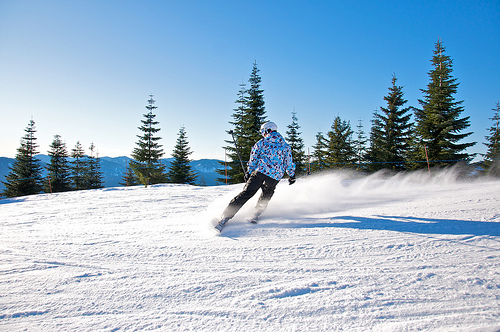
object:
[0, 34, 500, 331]
landscape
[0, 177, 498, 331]
snow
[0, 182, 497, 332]
ground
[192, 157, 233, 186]
hills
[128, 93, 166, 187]
pine trees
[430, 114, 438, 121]
pine needles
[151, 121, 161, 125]
branches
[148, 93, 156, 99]
tree tops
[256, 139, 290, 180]
back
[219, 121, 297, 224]
skiier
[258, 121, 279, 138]
helmet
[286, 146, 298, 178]
arm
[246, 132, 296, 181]
jacket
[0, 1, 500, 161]
sky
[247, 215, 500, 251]
shadow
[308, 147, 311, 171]
poles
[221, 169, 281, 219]
black pants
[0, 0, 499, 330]
photo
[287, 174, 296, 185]
black gloves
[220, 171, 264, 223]
leg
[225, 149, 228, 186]
pole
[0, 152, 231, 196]
distance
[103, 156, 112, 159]
top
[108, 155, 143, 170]
mountain